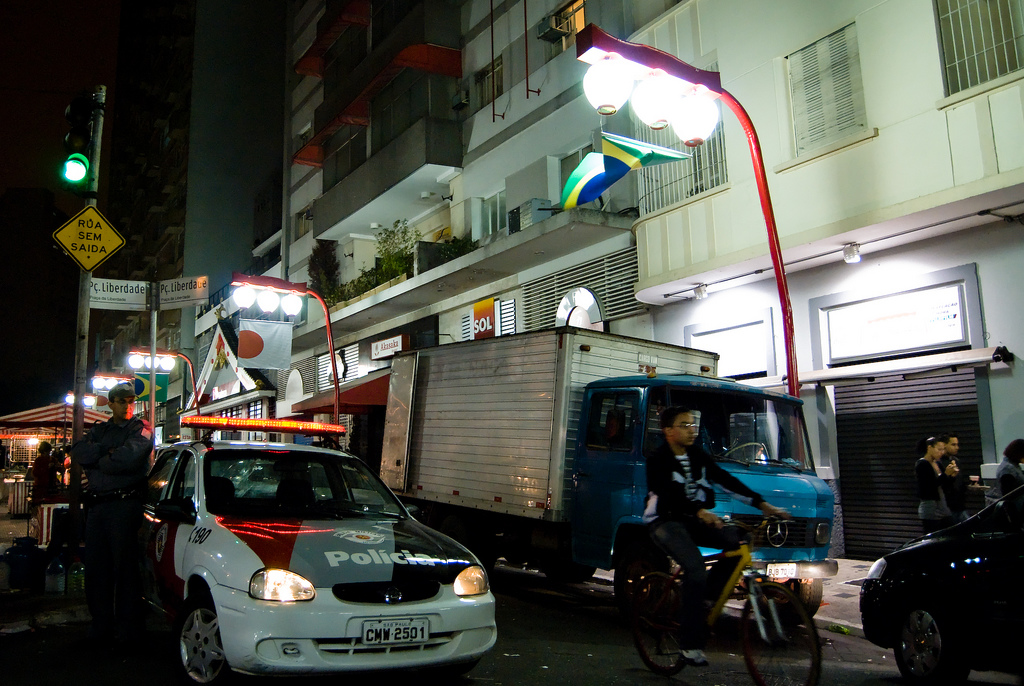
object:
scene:
[321, 548, 434, 567]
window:
[747, 20, 879, 177]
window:
[934, 1, 1024, 105]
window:
[622, 41, 731, 221]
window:
[811, 281, 984, 366]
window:
[473, 54, 508, 109]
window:
[482, 187, 510, 236]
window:
[462, 308, 476, 341]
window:
[496, 297, 520, 338]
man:
[640, 403, 791, 669]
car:
[115, 416, 495, 677]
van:
[378, 325, 833, 614]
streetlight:
[569, 21, 804, 396]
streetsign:
[55, 189, 131, 271]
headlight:
[250, 567, 315, 605]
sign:
[473, 315, 492, 334]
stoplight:
[58, 153, 90, 189]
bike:
[614, 515, 827, 686]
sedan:
[859, 479, 1023, 686]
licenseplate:
[362, 620, 430, 645]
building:
[214, 0, 1021, 545]